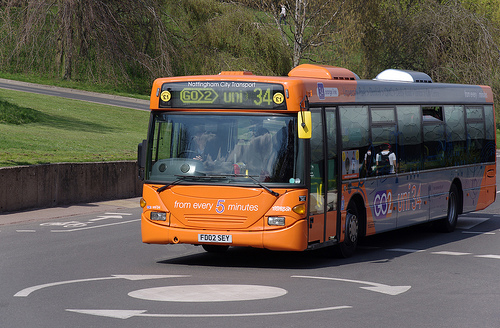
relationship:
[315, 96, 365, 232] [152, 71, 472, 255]
door on bus